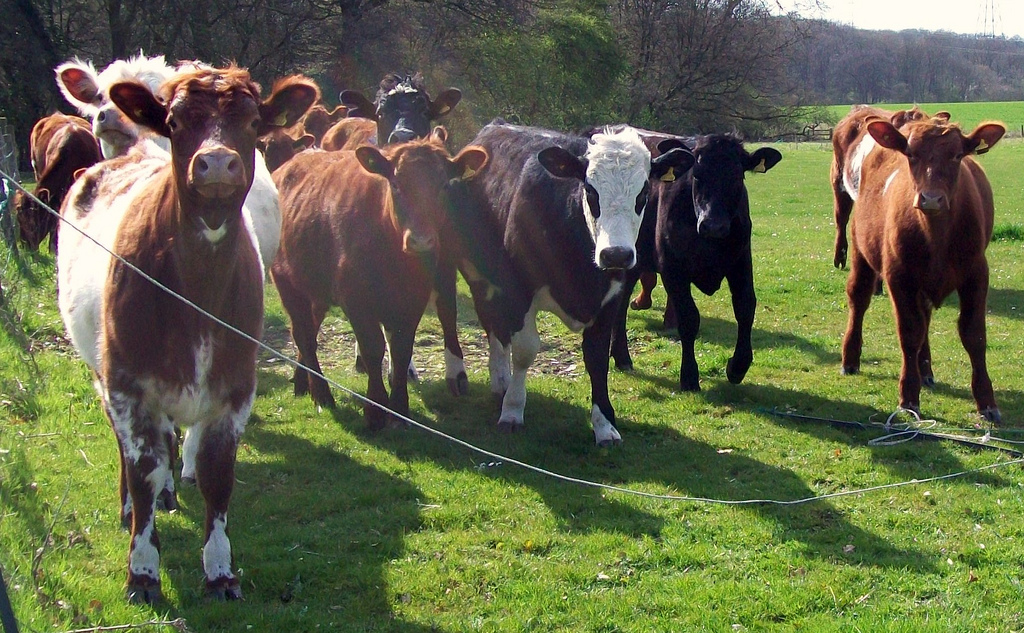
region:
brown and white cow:
[54, 75, 320, 600]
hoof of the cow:
[127, 574, 159, 600]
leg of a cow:
[105, 366, 167, 576]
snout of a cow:
[187, 147, 239, 202]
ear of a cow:
[108, 78, 169, 132]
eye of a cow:
[160, 112, 180, 132]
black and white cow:
[463, 123, 691, 436]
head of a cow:
[864, 116, 1002, 211]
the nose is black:
[598, 242, 633, 271]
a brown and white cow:
[52, 65, 325, 597]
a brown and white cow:
[269, 134, 484, 428]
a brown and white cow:
[833, 111, 999, 418]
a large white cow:
[58, 51, 275, 271]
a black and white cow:
[447, 112, 688, 449]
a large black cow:
[601, 122, 782, 389]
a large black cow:
[340, 73, 473, 393]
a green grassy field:
[6, 102, 1019, 631]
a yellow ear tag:
[660, 165, 677, 181]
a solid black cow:
[632, 120, 784, 396]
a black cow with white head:
[455, 105, 656, 453]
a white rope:
[13, 164, 984, 529]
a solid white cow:
[85, 48, 298, 282]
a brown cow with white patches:
[21, 72, 296, 586]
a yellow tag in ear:
[973, 133, 992, 162]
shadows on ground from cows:
[227, 366, 980, 624]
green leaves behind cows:
[482, 6, 629, 137]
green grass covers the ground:
[13, 91, 1022, 630]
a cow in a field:
[811, 111, 1005, 437]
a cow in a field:
[646, 131, 774, 373]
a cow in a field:
[455, 105, 642, 435]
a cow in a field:
[272, 114, 470, 440]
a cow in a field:
[48, 76, 258, 588]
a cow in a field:
[19, 104, 86, 256]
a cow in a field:
[331, 73, 453, 143]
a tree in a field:
[609, 3, 794, 141]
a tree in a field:
[448, 7, 617, 154]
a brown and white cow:
[841, 113, 1001, 420]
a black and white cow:
[457, 117, 689, 447]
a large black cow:
[634, 129, 781, 392]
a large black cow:
[340, 82, 458, 141]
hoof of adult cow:
[896, 401, 917, 420]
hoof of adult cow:
[921, 371, 934, 381]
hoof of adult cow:
[721, 356, 744, 388]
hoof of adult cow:
[591, 428, 624, 447]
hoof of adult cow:
[494, 409, 524, 430]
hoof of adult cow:
[124, 574, 166, 613]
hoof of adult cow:
[205, 570, 243, 605]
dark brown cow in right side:
[835, 118, 1007, 422]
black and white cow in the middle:
[465, 118, 687, 442]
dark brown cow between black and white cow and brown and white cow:
[257, 130, 482, 419]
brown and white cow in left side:
[50, 63, 325, 605]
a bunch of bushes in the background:
[0, 10, 820, 188]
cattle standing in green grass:
[4, 35, 1013, 611]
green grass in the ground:
[1, 101, 1017, 629]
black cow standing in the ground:
[633, 136, 776, 387]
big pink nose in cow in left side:
[186, 142, 253, 193]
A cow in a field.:
[422, 111, 641, 451]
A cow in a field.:
[594, 106, 766, 394]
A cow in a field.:
[838, 112, 1004, 408]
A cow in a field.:
[819, 100, 931, 215]